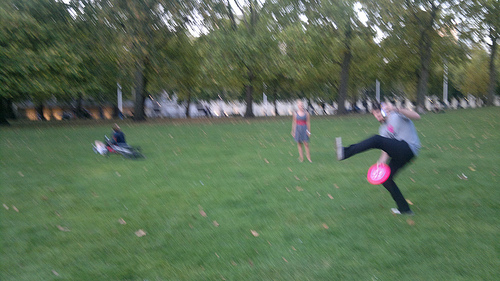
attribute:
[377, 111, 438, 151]
shirt — blue, short sleeved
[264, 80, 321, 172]
woman — tall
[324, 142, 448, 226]
frisbee — pink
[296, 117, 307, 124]
belt — red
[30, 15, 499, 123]
trees — leafy, tall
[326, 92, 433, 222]
man — playing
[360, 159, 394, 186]
frisbee — pink, round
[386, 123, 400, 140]
design — red and gray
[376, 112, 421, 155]
shirt — grey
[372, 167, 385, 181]
design — white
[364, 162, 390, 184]
frisbee — pink, round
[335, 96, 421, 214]
man — playing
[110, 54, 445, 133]
trees — leafy, tall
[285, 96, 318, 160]
woman — tall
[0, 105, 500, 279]
grass — green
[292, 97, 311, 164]
woman — standing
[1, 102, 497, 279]
field — grassy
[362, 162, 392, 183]
frisbee — pink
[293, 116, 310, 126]
belt — red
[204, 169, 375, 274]
grass — green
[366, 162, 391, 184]
frisbee — pink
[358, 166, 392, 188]
frisbee — red